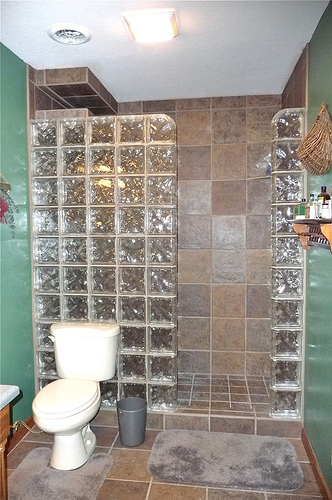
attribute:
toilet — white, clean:
[32, 318, 124, 471]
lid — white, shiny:
[48, 322, 118, 335]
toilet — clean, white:
[29, 320, 121, 466]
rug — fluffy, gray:
[146, 427, 306, 490]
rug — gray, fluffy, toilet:
[10, 446, 110, 499]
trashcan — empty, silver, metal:
[116, 396, 146, 444]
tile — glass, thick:
[31, 114, 178, 406]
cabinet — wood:
[0, 416, 12, 495]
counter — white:
[0, 383, 20, 406]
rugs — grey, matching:
[18, 429, 312, 498]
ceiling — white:
[6, 4, 319, 101]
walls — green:
[0, 48, 32, 426]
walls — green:
[300, 7, 320, 453]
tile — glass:
[275, 112, 302, 423]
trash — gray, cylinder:
[115, 395, 146, 446]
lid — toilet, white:
[31, 376, 99, 417]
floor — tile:
[100, 411, 304, 498]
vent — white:
[46, 24, 91, 45]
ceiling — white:
[3, 2, 317, 69]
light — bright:
[119, 7, 179, 45]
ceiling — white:
[2, 1, 317, 61]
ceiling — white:
[3, 2, 321, 79]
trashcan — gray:
[117, 394, 147, 446]